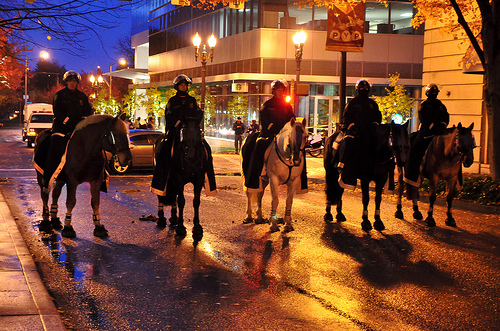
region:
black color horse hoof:
[61, 226, 78, 238]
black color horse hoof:
[92, 225, 110, 238]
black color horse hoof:
[39, 218, 52, 229]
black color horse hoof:
[51, 217, 62, 229]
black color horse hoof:
[173, 220, 187, 235]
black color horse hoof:
[191, 220, 203, 232]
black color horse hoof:
[156, 213, 167, 225]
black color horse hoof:
[361, 217, 373, 231]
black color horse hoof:
[373, 218, 385, 232]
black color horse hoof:
[323, 207, 333, 220]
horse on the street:
[50, 114, 125, 241]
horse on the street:
[142, 115, 223, 246]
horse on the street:
[229, 107, 309, 223]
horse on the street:
[314, 118, 379, 239]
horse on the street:
[396, 122, 478, 225]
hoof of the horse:
[64, 227, 82, 247]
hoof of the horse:
[92, 222, 112, 241]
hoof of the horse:
[142, 217, 164, 232]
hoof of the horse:
[172, 232, 191, 248]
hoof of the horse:
[252, 214, 279, 229]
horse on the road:
[65, 18, 478, 289]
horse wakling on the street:
[54, 46, 491, 262]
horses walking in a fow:
[32, 43, 495, 287]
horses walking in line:
[29, 62, 499, 243]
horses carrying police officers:
[54, 59, 474, 312]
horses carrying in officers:
[43, 56, 495, 225]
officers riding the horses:
[19, 32, 499, 271]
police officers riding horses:
[14, 46, 497, 267]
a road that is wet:
[64, 123, 443, 325]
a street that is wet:
[72, 134, 342, 323]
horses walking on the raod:
[75, 57, 485, 258]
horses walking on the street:
[51, 56, 468, 244]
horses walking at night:
[24, 68, 499, 295]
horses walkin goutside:
[5, 33, 497, 265]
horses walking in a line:
[47, 69, 499, 296]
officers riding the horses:
[25, 52, 455, 266]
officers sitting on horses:
[43, 34, 494, 250]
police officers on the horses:
[19, 57, 496, 247]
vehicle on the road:
[91, 70, 301, 296]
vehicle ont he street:
[94, 73, 243, 196]